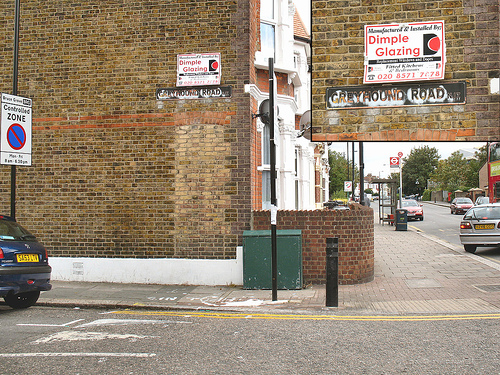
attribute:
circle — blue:
[1, 116, 72, 178]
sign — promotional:
[172, 51, 222, 86]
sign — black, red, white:
[362, 21, 443, 83]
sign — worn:
[323, 82, 456, 112]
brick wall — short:
[248, 207, 377, 289]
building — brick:
[1, 1, 326, 286]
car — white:
[430, 177, 495, 257]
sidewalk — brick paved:
[35, 224, 498, 316]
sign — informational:
[0, 91, 32, 171]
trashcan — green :
[391, 205, 408, 233]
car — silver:
[449, 205, 498, 263]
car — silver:
[394, 190, 424, 229]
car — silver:
[0, 198, 53, 320]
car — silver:
[447, 195, 473, 219]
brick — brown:
[76, 67, 221, 220]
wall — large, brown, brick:
[0, 0, 250, 260]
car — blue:
[4, 217, 57, 315]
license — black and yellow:
[460, 216, 490, 238]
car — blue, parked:
[459, 197, 497, 252]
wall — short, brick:
[246, 222, 377, 288]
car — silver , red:
[458, 201, 498, 252]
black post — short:
[321, 227, 346, 299]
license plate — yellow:
[16, 252, 41, 261]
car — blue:
[0, 215, 52, 310]